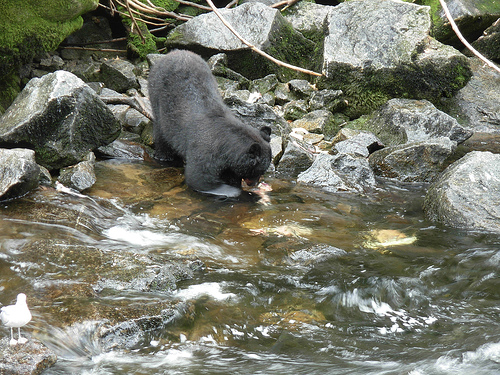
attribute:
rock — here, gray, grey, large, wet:
[10, 70, 127, 163]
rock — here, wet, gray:
[320, 7, 460, 96]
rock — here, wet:
[168, 6, 304, 89]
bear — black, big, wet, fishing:
[142, 48, 280, 188]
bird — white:
[9, 293, 35, 345]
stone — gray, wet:
[4, 340, 49, 374]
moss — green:
[337, 60, 468, 116]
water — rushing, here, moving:
[2, 141, 499, 372]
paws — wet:
[216, 187, 266, 208]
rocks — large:
[4, 1, 499, 206]